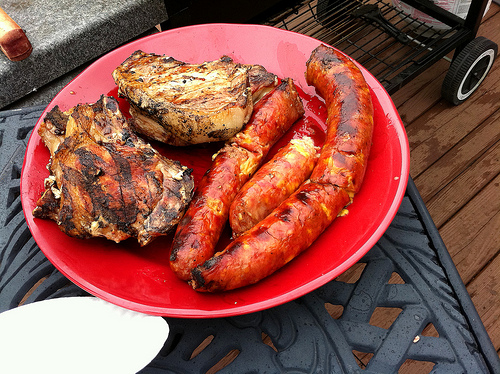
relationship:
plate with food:
[20, 23, 409, 320] [122, 92, 292, 228]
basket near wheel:
[263, 1, 466, 93] [437, 32, 498, 104]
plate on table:
[12, 19, 410, 321] [2, 105, 497, 371]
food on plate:
[31, 42, 372, 292] [12, 19, 410, 321]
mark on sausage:
[188, 256, 219, 295] [178, 40, 376, 290]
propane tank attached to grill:
[377, 0, 494, 96] [303, 3, 498, 88]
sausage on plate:
[217, 110, 321, 237] [28, 225, 181, 311]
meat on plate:
[30, 92, 198, 245] [28, 13, 438, 339]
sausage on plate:
[315, 47, 370, 187] [28, 13, 438, 339]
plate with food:
[20, 23, 409, 320] [22, 42, 368, 251]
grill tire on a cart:
[441, 35, 498, 106] [275, 3, 498, 108]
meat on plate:
[30, 92, 202, 245] [12, 19, 410, 321]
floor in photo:
[178, 5, 499, 372] [2, 2, 499, 372]